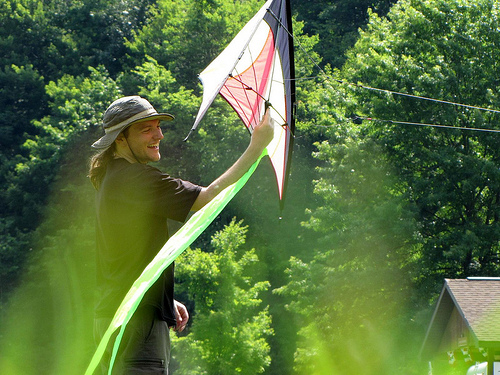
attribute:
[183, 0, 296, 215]
kite — red, long, blue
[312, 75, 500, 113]
zip — running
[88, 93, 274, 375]
man — here, smiling, dressed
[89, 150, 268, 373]
tail — green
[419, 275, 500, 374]
building — wooden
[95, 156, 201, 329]
top — black, short sleeved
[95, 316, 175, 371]
pants — grey